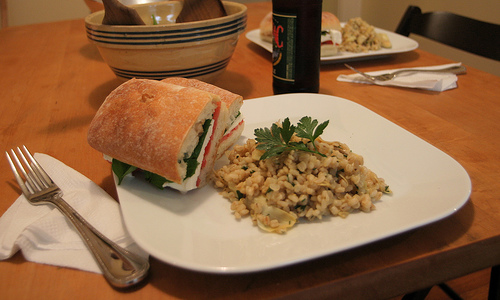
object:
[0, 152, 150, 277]
napkin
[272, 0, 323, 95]
beer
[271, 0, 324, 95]
beer bottle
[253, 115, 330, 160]
vegetable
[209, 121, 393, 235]
eggs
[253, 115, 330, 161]
cilantro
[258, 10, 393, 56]
food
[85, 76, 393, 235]
food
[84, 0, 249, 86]
bowl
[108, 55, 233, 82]
black stripes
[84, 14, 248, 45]
black stripes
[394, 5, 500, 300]
chair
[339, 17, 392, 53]
rice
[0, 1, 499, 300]
table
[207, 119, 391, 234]
rice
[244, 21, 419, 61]
plate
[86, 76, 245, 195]
sandwich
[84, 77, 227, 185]
bread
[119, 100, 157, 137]
brown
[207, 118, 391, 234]
scrambled eggs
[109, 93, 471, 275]
dish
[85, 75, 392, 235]
lunch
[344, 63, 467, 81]
fork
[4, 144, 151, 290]
fork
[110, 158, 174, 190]
spinach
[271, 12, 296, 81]
label